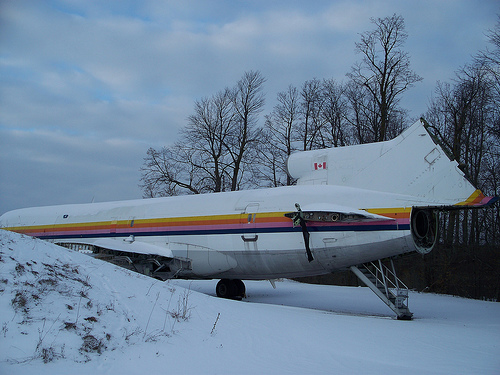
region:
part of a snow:
[428, 276, 440, 302]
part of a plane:
[234, 185, 239, 255]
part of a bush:
[440, 271, 442, 297]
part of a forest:
[434, 225, 459, 283]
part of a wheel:
[226, 270, 237, 287]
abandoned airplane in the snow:
[16, 119, 492, 322]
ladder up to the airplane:
[353, 258, 415, 317]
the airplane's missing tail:
[413, 115, 492, 206]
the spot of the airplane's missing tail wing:
[281, 208, 382, 223]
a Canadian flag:
[313, 162, 327, 169]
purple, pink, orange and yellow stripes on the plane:
[22, 210, 409, 239]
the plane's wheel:
[210, 277, 247, 301]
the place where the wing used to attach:
[61, 241, 176, 281]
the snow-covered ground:
[0, 232, 499, 369]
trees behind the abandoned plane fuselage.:
[145, 15, 495, 301]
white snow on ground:
[179, 287, 214, 335]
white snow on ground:
[236, 304, 298, 369]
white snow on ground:
[301, 286, 331, 325]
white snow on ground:
[386, 311, 412, 348]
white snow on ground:
[450, 318, 480, 351]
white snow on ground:
[429, 330, 451, 358]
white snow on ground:
[376, 320, 411, 360]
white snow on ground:
[289, 306, 322, 330]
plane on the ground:
[0, 118, 490, 320]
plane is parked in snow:
[1, 118, 498, 373]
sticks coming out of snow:
[0, 219, 220, 359]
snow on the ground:
[1, 229, 498, 372]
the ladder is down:
[350, 260, 413, 320]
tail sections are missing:
[286, 119, 491, 224]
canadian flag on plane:
[314, 160, 326, 172]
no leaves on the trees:
[139, 12, 499, 246]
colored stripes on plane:
[0, 190, 490, 240]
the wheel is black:
[217, 277, 245, 299]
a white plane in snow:
[12, 99, 496, 309]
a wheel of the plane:
[218, 270, 257, 310]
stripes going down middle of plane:
[19, 209, 401, 252]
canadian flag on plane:
[308, 152, 355, 183]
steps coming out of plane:
[347, 253, 442, 357]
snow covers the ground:
[1, 218, 483, 374]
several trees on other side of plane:
[133, 81, 493, 225]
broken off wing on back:
[261, 189, 421, 242]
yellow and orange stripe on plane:
[10, 199, 418, 236]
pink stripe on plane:
[21, 215, 404, 239]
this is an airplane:
[25, 116, 427, 328]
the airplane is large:
[59, 161, 377, 298]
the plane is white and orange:
[139, 178, 313, 270]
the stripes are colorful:
[172, 205, 290, 251]